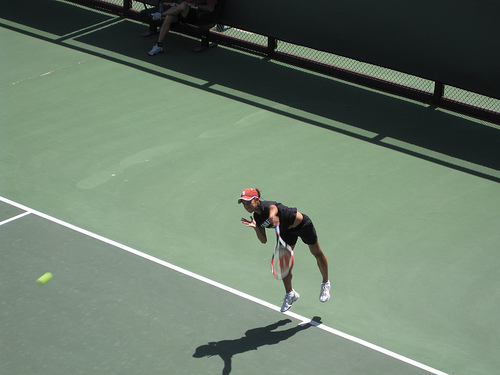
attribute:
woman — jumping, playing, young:
[198, 192, 335, 306]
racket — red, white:
[276, 223, 298, 289]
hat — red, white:
[229, 184, 261, 206]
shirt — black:
[265, 198, 291, 224]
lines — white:
[43, 220, 249, 297]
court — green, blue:
[49, 104, 484, 374]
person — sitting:
[146, 2, 202, 22]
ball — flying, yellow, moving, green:
[37, 260, 62, 282]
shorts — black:
[276, 226, 317, 249]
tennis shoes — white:
[284, 292, 344, 306]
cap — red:
[237, 184, 265, 203]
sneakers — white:
[280, 289, 334, 311]